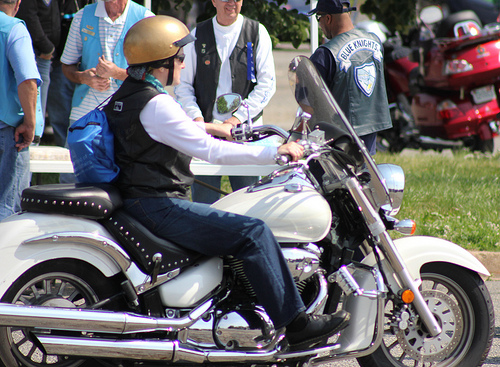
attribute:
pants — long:
[117, 170, 327, 335]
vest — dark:
[182, 15, 262, 131]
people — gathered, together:
[0, 6, 440, 364]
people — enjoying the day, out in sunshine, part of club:
[1, 4, 490, 360]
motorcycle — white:
[0, 51, 487, 334]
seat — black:
[0, 151, 238, 283]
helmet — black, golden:
[113, 0, 205, 96]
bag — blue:
[57, 66, 133, 209]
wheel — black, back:
[0, 215, 163, 364]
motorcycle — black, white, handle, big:
[0, 50, 496, 364]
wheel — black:
[344, 231, 489, 363]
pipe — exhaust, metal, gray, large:
[0, 291, 212, 363]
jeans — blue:
[104, 175, 318, 335]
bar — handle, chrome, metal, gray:
[244, 93, 351, 200]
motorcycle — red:
[375, 0, 496, 160]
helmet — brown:
[113, 2, 216, 83]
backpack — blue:
[55, 88, 147, 211]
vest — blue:
[99, 81, 188, 191]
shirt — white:
[134, 92, 280, 168]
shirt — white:
[140, 91, 283, 172]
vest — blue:
[99, 73, 198, 193]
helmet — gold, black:
[121, 15, 199, 67]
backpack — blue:
[68, 103, 122, 189]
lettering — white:
[69, 150, 99, 179]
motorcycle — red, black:
[390, 0, 499, 137]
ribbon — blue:
[245, 33, 259, 83]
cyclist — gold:
[87, 8, 338, 364]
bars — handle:
[226, 116, 335, 201]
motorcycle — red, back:
[388, 21, 481, 117]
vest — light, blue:
[42, 1, 141, 147]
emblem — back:
[97, 87, 136, 134]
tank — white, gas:
[218, 168, 355, 258]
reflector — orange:
[390, 273, 427, 318]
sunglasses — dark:
[160, 37, 202, 80]